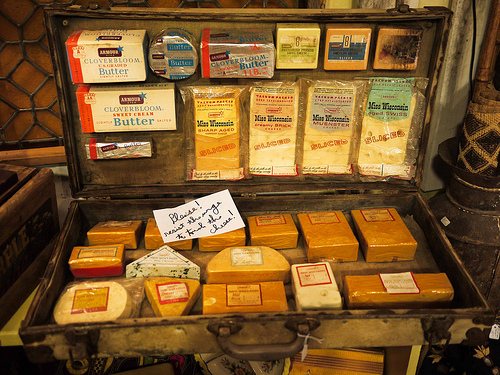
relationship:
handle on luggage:
[210, 324, 315, 360] [20, 6, 493, 363]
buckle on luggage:
[421, 315, 458, 351] [20, 6, 493, 363]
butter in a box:
[65, 30, 150, 85] [67, 28, 149, 84]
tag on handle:
[295, 331, 323, 363] [210, 324, 315, 360]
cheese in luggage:
[189, 88, 243, 182] [20, 6, 493, 363]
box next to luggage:
[1, 159, 61, 319] [20, 6, 493, 363]